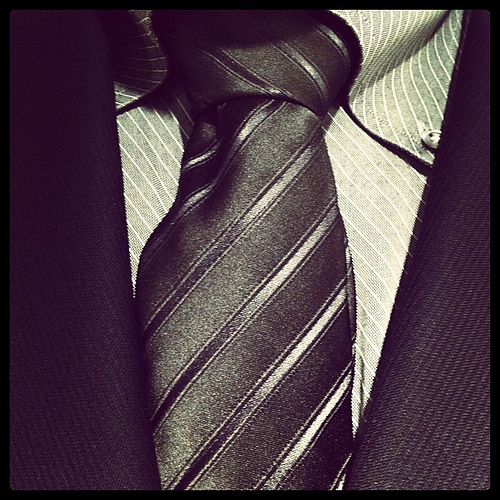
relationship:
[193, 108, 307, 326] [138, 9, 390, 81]
tie on neck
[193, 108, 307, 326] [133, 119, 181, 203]
tie on shirt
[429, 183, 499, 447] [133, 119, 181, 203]
jacket on shirt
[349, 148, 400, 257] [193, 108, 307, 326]
stripes on tie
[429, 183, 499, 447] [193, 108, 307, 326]
jacket by tie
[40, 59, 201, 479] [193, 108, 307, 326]
suit with tie